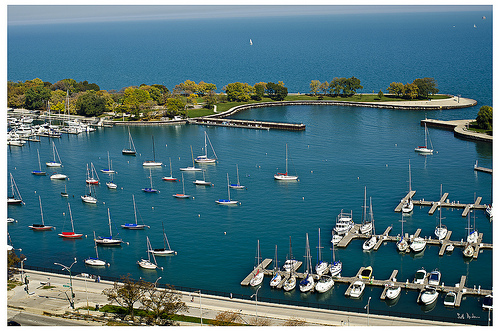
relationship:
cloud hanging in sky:
[8, 7, 485, 25] [1, 9, 496, 19]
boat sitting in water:
[313, 273, 333, 294] [18, 128, 468, 290]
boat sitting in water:
[416, 280, 440, 308] [18, 128, 468, 290]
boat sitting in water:
[136, 234, 161, 270] [18, 128, 468, 290]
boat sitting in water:
[81, 229, 110, 269] [18, 128, 468, 290]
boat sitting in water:
[118, 190, 147, 231] [18, 128, 468, 290]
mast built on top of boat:
[349, 181, 370, 225] [321, 213, 358, 236]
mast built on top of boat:
[64, 198, 75, 231] [56, 199, 86, 240]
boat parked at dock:
[248, 240, 265, 290] [249, 271, 491, 295]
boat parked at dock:
[267, 240, 283, 287] [249, 271, 491, 295]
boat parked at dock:
[296, 228, 315, 293] [249, 271, 491, 295]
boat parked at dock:
[312, 270, 332, 293] [249, 271, 491, 295]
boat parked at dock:
[346, 277, 366, 299] [249, 271, 491, 295]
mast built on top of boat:
[284, 144, 288, 174] [271, 142, 298, 181]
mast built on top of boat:
[224, 172, 231, 199] [212, 196, 241, 208]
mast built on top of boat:
[66, 202, 75, 230] [56, 202, 83, 237]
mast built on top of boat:
[177, 160, 192, 194] [168, 157, 193, 204]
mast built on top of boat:
[270, 170, 300, 183] [268, 140, 303, 184]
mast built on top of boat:
[101, 206, 117, 236] [91, 206, 123, 249]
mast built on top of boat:
[251, 236, 264, 271] [247, 235, 267, 286]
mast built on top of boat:
[420, 116, 438, 151] [412, 110, 437, 159]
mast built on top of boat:
[123, 125, 137, 150] [120, 120, 136, 157]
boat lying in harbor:
[244, 235, 264, 288] [9, 84, 485, 322]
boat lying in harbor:
[346, 277, 366, 299] [9, 84, 485, 322]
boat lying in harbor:
[384, 281, 402, 301] [9, 84, 485, 322]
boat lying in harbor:
[356, 261, 375, 282] [9, 84, 485, 322]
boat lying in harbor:
[416, 280, 440, 308] [9, 84, 485, 322]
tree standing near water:
[267, 81, 288, 101] [25, 23, 488, 74]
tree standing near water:
[309, 75, 321, 95] [25, 23, 488, 74]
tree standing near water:
[180, 77, 199, 98] [25, 23, 488, 74]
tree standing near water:
[383, 78, 405, 97] [25, 23, 488, 74]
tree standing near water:
[413, 75, 439, 100] [96, 133, 441, 266]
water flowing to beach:
[408, 94, 483, 131] [366, 94, 476, 110]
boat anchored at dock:
[346, 277, 366, 299] [239, 256, 485, 306]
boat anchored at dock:
[356, 261, 375, 282] [239, 256, 485, 306]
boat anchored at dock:
[406, 232, 426, 253] [335, 215, 485, 261]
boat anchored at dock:
[444, 242, 454, 252] [335, 215, 485, 261]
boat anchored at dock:
[399, 156, 416, 212] [392, 185, 484, 215]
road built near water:
[8, 264, 470, 325] [10, 10, 485, 323]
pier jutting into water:
[181, 105, 311, 139] [10, 10, 485, 323]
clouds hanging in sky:
[156, 24, 410, 138] [80, 3, 202, 30]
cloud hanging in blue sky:
[8, 7, 485, 25] [8, 2, 494, 24]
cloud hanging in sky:
[8, 7, 485, 25] [17, 0, 413, 18]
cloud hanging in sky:
[8, 7, 485, 25] [98, 17, 140, 28]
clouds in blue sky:
[156, 24, 410, 138] [6, 5, 491, 27]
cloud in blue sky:
[8, 7, 485, 25] [6, 5, 491, 27]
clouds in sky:
[404, 43, 454, 70] [12, 8, 491, 27]